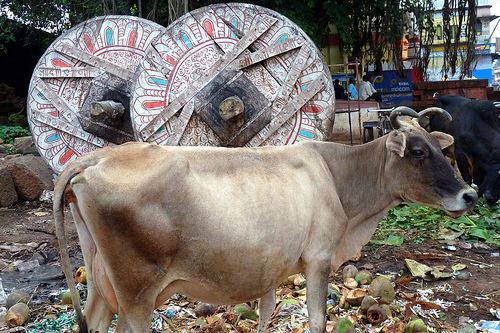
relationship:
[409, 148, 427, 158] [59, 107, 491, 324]
eye of cow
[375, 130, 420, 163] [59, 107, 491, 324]
ear of cow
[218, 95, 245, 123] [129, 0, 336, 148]
axel of wheel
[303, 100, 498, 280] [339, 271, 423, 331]
cow in garbage heap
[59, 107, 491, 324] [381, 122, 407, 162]
cow has ear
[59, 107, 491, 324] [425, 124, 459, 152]
cow has ear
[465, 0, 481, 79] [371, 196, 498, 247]
tree fronds overhang pile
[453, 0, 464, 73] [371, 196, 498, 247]
tree fronds overhang pile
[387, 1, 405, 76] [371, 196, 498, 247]
tree fronds overhang pile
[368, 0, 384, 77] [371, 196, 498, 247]
tree fronds overhang pile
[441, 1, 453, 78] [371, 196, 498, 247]
tree fronds overhang pile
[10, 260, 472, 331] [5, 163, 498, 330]
vegetation lying on ground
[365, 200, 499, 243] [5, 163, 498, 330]
vegetation lying on ground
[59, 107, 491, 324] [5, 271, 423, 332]
cow in garbage heap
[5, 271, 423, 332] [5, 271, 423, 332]
garbage heap of garbage heap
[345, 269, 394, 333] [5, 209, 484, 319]
fruit on ground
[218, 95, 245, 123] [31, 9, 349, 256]
axel on wheel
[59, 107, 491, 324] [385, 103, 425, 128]
cow has horn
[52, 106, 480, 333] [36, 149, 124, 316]
cow has tail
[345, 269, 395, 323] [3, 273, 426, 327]
fruit on ground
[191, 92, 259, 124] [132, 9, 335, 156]
axel of wheel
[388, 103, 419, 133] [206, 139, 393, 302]
horn of cow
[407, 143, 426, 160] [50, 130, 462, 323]
eye of cow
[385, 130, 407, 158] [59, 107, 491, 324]
ear of cow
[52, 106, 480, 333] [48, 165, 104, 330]
cow has tail